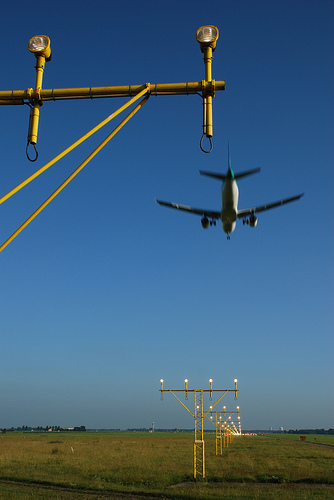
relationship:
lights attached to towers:
[23, 17, 228, 56] [5, 57, 231, 161]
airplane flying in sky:
[151, 156, 307, 240] [57, 250, 181, 350]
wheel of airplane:
[242, 220, 247, 228] [151, 156, 307, 240]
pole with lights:
[158, 387, 239, 478] [155, 374, 243, 400]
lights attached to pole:
[155, 374, 243, 400] [158, 387, 239, 478]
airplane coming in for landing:
[151, 156, 307, 240] [217, 428, 333, 470]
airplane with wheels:
[151, 156, 307, 240] [206, 215, 252, 238]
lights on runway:
[155, 374, 243, 400] [184, 414, 332, 494]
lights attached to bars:
[155, 374, 243, 400] [158, 388, 252, 480]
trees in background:
[303, 426, 329, 434] [7, 413, 333, 448]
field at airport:
[10, 437, 333, 478] [3, 418, 332, 498]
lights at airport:
[155, 374, 243, 400] [3, 423, 333, 494]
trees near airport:
[303, 426, 329, 434] [3, 423, 333, 494]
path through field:
[160, 473, 333, 496] [88, 436, 166, 486]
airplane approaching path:
[151, 156, 307, 240] [0, 479, 334, 499]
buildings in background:
[1, 418, 89, 435] [3, 419, 333, 444]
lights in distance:
[155, 374, 243, 400] [149, 372, 267, 475]